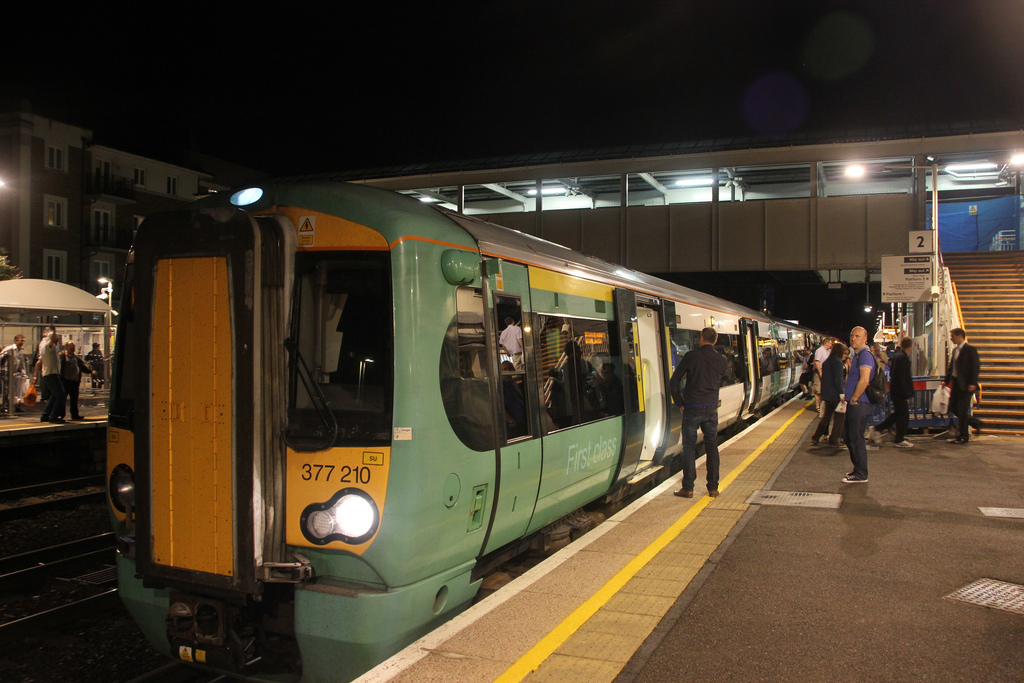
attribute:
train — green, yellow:
[103, 182, 832, 681]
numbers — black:
[301, 460, 373, 484]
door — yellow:
[153, 255, 243, 580]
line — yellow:
[497, 391, 818, 680]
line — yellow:
[530, 265, 620, 304]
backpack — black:
[857, 352, 893, 398]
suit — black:
[949, 346, 980, 433]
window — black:
[536, 312, 582, 439]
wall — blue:
[928, 198, 1024, 252]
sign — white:
[911, 226, 933, 254]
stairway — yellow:
[943, 252, 1024, 433]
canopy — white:
[0, 277, 114, 310]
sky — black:
[1, 3, 1016, 175]